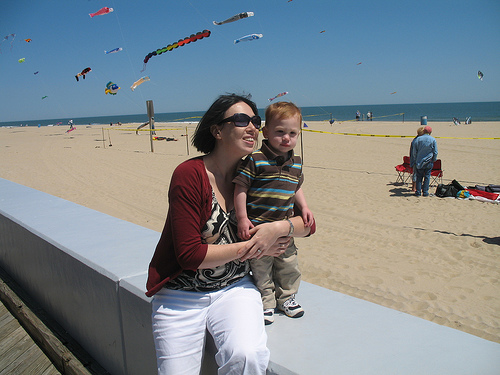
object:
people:
[410, 125, 438, 197]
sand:
[0, 122, 207, 233]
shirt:
[413, 134, 439, 170]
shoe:
[263, 306, 274, 326]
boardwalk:
[0, 270, 97, 375]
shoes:
[277, 297, 305, 318]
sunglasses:
[217, 112, 261, 128]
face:
[222, 100, 262, 155]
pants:
[149, 273, 271, 375]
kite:
[234, 33, 265, 45]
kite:
[212, 11, 255, 26]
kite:
[139, 28, 212, 73]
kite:
[129, 74, 151, 92]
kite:
[89, 6, 114, 18]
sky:
[0, 0, 500, 127]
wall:
[0, 176, 500, 375]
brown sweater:
[144, 154, 245, 298]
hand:
[301, 210, 316, 228]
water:
[0, 101, 500, 127]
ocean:
[0, 101, 500, 126]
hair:
[265, 101, 303, 132]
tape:
[431, 136, 500, 140]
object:
[283, 218, 295, 237]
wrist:
[271, 220, 284, 237]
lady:
[141, 90, 317, 375]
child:
[230, 100, 315, 325]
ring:
[257, 249, 262, 254]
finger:
[240, 243, 259, 263]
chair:
[394, 156, 414, 185]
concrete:
[267, 279, 500, 375]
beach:
[0, 120, 500, 344]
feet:
[276, 298, 305, 318]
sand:
[293, 120, 500, 344]